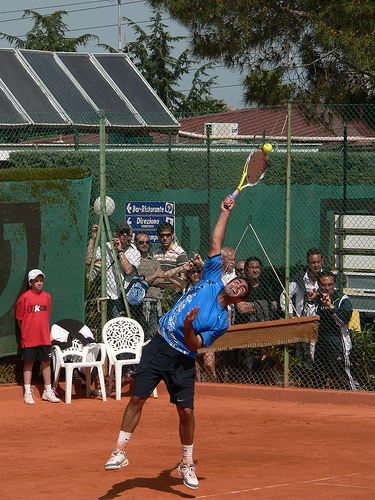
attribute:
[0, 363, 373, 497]
floor — tennis court, brown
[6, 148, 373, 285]
wall — green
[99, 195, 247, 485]
man — jumping 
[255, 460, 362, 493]
line — white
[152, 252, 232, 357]
shirt — blue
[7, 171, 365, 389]
wall — green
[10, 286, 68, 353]
shirt — red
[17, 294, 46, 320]
letter — white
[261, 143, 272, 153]
ball — tennis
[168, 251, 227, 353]
shirt — blue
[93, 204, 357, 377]
fence — chain link